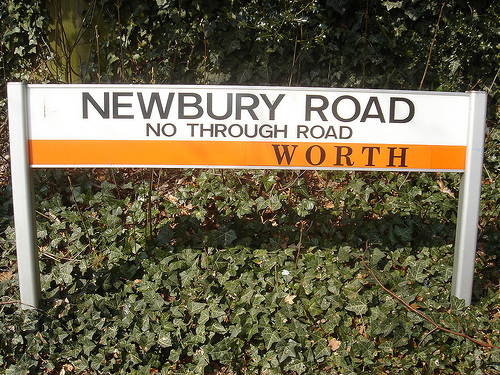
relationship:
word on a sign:
[263, 138, 415, 175] [1, 69, 495, 342]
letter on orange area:
[270, 144, 296, 165] [27, 139, 466, 169]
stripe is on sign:
[28, 139, 465, 171] [24, 82, 469, 174]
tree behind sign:
[55, 5, 286, 86] [4, 78, 492, 317]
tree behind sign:
[274, 0, 469, 101] [4, 78, 492, 317]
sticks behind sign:
[25, 14, 118, 90] [1, 69, 495, 342]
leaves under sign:
[26, 180, 473, 367] [4, 78, 492, 317]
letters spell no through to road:
[144, 123, 353, 140] [231, 225, 395, 332]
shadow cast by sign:
[43, 205, 498, 324] [4, 78, 492, 317]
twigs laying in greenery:
[355, 247, 447, 346] [282, 231, 408, 354]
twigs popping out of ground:
[361, 254, 490, 356] [2, 72, 498, 369]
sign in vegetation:
[21, 74, 483, 174] [0, 41, 498, 370]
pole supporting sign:
[4, 80, 37, 330] [0, 87, 479, 163]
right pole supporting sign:
[450, 85, 487, 309] [11, 72, 475, 184]